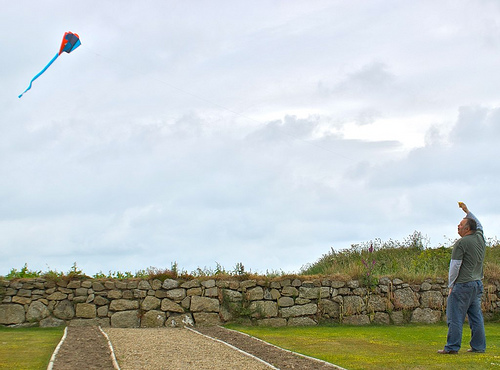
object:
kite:
[11, 32, 81, 101]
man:
[443, 202, 492, 354]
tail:
[17, 49, 63, 98]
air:
[0, 1, 496, 275]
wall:
[1, 275, 498, 325]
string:
[59, 51, 464, 207]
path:
[46, 327, 350, 369]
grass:
[1, 326, 67, 369]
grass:
[242, 322, 499, 368]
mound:
[302, 229, 499, 276]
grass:
[313, 233, 498, 277]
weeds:
[405, 229, 425, 261]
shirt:
[446, 259, 461, 288]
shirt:
[449, 214, 487, 283]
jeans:
[446, 279, 486, 352]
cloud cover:
[1, 101, 499, 169]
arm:
[458, 202, 485, 238]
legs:
[444, 281, 471, 350]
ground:
[1, 327, 497, 367]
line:
[94, 326, 123, 368]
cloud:
[374, 100, 500, 177]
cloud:
[320, 62, 417, 117]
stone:
[343, 295, 366, 315]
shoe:
[436, 350, 459, 355]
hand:
[459, 202, 469, 214]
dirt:
[57, 321, 109, 369]